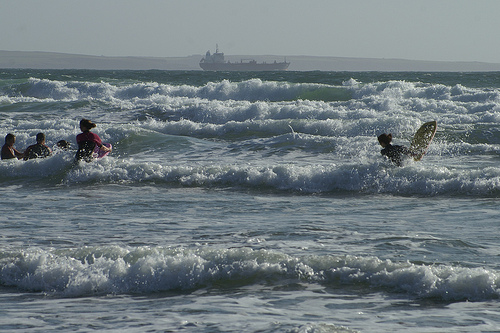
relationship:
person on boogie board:
[372, 126, 412, 165] [406, 117, 440, 162]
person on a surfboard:
[372, 126, 412, 165] [406, 117, 440, 162]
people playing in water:
[1, 113, 116, 175] [6, 69, 497, 331]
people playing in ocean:
[1, 113, 116, 175] [6, 69, 497, 331]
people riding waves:
[1, 113, 116, 175] [6, 69, 497, 331]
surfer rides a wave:
[372, 126, 412, 165] [280, 101, 497, 201]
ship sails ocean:
[197, 40, 293, 73] [6, 69, 497, 331]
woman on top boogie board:
[372, 126, 412, 165] [406, 117, 440, 162]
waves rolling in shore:
[6, 69, 497, 331] [6, 48, 487, 72]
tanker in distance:
[197, 40, 293, 73] [6, 48, 487, 72]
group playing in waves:
[1, 113, 116, 175] [6, 69, 497, 331]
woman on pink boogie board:
[372, 126, 412, 165] [406, 117, 440, 162]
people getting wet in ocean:
[1, 113, 116, 175] [6, 69, 497, 331]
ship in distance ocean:
[197, 40, 293, 73] [6, 69, 497, 331]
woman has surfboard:
[372, 126, 412, 165] [406, 117, 440, 162]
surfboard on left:
[406, 117, 440, 162] [469, 5, 494, 331]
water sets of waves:
[6, 69, 497, 331] [6, 73, 495, 302]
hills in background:
[6, 48, 487, 72] [3, 31, 499, 88]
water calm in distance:
[5, 66, 494, 81] [6, 48, 487, 72]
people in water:
[1, 113, 116, 175] [6, 69, 497, 331]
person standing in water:
[372, 126, 412, 165] [6, 69, 497, 331]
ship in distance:
[197, 40, 293, 73] [6, 48, 487, 72]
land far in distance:
[6, 48, 487, 72] [3, 31, 499, 88]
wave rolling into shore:
[0, 232, 489, 305] [4, 313, 499, 330]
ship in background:
[197, 40, 293, 73] [3, 31, 499, 88]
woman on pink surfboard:
[372, 126, 412, 165] [406, 117, 440, 162]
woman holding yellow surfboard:
[372, 126, 412, 165] [406, 117, 440, 162]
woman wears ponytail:
[372, 126, 412, 165] [373, 129, 402, 154]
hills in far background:
[6, 48, 487, 72] [3, 31, 499, 88]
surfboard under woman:
[96, 138, 115, 158] [72, 116, 110, 163]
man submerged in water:
[52, 134, 73, 153] [6, 69, 497, 331]